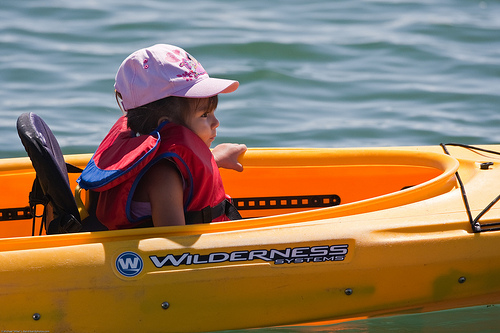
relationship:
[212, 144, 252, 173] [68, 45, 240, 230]
hand on child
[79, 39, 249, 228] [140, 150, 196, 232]
child has arm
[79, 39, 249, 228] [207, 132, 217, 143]
child has mouth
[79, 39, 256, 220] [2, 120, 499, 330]
child in kayak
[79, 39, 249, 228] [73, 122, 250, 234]
child wears vest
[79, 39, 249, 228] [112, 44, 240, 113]
child wears cap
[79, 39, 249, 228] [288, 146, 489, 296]
child in kayak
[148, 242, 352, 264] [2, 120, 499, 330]
word on kayak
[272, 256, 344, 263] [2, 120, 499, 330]
word on kayak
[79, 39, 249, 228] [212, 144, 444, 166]
child holds kayak side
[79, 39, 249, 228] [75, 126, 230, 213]
child wears life jacket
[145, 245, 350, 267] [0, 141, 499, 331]
writing on kayak